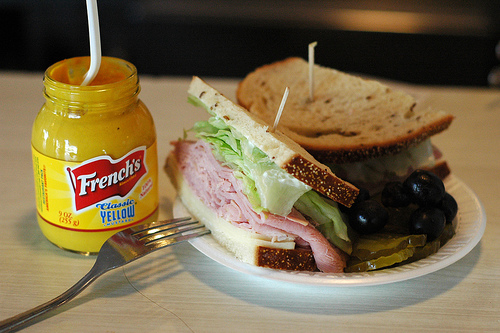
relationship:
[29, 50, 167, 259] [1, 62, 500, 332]
mustard jar on table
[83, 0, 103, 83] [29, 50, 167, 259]
utensil in mustard jar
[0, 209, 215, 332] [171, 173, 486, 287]
fork on paper plate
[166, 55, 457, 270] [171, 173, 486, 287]
sandwich on paper plate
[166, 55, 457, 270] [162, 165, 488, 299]
sandwich on paper plate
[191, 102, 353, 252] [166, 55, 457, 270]
lettuce on sandwich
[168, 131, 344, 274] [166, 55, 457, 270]
ham on sandwich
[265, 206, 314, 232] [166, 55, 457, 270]
cheese on sandwich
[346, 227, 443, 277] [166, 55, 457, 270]
pickles by sandwich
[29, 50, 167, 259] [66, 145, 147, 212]
mustard jar with flag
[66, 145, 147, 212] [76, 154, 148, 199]
flag says french's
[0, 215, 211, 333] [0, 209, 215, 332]
fork on fork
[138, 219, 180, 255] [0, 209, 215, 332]
light reflecting on fork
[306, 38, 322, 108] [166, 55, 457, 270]
toothpick in sandwich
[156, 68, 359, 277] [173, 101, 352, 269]
sandwich half with lettuce and ham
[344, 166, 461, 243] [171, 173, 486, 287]
black olives on paper plate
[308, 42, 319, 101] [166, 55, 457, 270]
toothpick in sandwich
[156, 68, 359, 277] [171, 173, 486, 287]
sandwich half on paper plate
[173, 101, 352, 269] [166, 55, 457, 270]
lettuce and ham in sandwich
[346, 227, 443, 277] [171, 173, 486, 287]
pickles on paper plate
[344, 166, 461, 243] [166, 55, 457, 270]
black olives on sandwich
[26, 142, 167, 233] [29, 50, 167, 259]
label on mustard jar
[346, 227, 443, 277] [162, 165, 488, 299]
pickles on paper plate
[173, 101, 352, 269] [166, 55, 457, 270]
lettuce and ham on sandwich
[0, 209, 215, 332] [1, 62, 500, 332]
fork on table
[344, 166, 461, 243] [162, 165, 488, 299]
black olives on paper plate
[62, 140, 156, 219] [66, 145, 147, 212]
flag with flag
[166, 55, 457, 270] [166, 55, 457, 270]
bread on sandwich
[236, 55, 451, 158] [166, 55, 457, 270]
bread on sandwich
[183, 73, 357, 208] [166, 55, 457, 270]
bread on sandwich